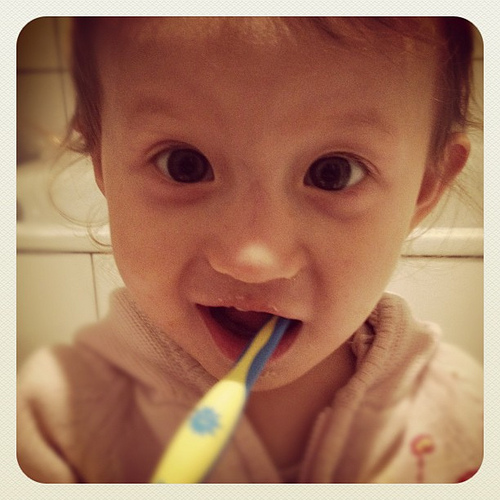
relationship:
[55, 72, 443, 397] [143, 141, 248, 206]
child has eye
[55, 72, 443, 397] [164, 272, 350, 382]
child has mouth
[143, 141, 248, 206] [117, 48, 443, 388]
eye of kid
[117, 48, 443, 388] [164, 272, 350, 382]
kid has mouth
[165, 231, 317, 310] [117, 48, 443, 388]
nose of kid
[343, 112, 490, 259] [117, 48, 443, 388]
ear of kid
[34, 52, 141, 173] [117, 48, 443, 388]
bang of kid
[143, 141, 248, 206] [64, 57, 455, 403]
eye on face